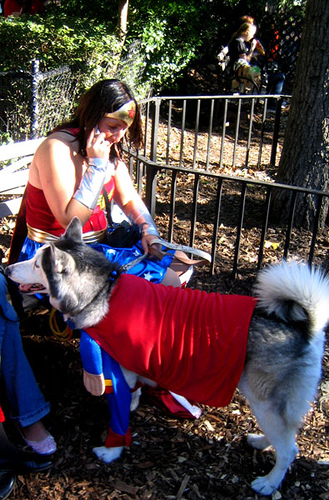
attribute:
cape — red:
[86, 270, 258, 409]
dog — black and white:
[2, 212, 328, 499]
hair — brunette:
[44, 72, 146, 154]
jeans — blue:
[2, 326, 48, 426]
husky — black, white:
[3, 216, 328, 491]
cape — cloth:
[1, 220, 55, 239]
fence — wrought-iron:
[133, 66, 313, 273]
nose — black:
[1, 265, 10, 278]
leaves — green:
[147, 25, 162, 39]